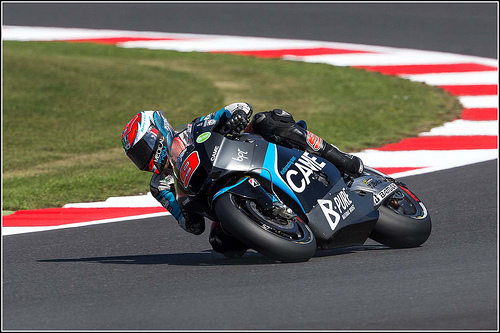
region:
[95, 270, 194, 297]
freshly painted gray paint on track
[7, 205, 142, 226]
large section of pink paint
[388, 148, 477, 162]
white paint on side of track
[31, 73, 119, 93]
freshly cut green grass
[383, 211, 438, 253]
over sized black wheel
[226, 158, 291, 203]
blue cord on front of bike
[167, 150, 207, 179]
gray and orange sign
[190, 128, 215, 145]
green and white circle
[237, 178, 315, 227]
struts on side of bike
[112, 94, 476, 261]
rider on multi colored bike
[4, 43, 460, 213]
grass infield on the race track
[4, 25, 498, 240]
red and white line on inside of curve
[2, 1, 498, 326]
black paved race track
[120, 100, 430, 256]
motorcycle racer on a motorcycle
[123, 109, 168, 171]
the motorcycle racer's helmet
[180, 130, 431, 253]
the black and blue motorcycle with a red number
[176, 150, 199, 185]
red number nine on the bike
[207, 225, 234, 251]
the racer's right knee on the track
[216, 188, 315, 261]
the front wheel of the motorcycle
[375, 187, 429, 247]
the rear wheel of the motorcycle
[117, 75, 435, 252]
man riding motorcycle on course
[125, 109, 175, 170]
motorcycle helmet on man's head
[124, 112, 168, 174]
red white and blue helmet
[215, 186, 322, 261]
front black wheel of bike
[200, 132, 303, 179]
black and blue frame of bike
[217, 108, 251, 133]
black riding gloves on hand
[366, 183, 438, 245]
thick black wheel of bike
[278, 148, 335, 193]
white writing on side of bike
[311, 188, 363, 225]
white writing on bottom of bike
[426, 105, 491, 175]
red and white stripes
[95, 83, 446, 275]
Man is leaning on motorbike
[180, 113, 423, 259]
This is a motorbike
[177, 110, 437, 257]
The bike is leaning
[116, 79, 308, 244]
The man is leaning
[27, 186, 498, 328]
This is an asphalt track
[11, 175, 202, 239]
The track border is red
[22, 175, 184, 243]
The track border is white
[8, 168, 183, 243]
The track border is striped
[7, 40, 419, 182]
The patch of grass is green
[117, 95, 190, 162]
The man is wearing a helmet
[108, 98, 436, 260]
racing motor cycle and rider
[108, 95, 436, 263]
motorcycle racer executing tight turn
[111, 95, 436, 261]
motorcycle racer tilted far right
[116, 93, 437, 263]
racing motorcycle with black and blue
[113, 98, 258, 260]
motorcycle racer in steep turn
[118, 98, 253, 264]
motorcycle rider wearing white helmet with red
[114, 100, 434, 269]
racing style motorcycle on track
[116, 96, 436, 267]
motorcycle turning on racetrack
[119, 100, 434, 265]
speeding motorcycle turning on track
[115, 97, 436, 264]
motorcycle racer driving on race track curve